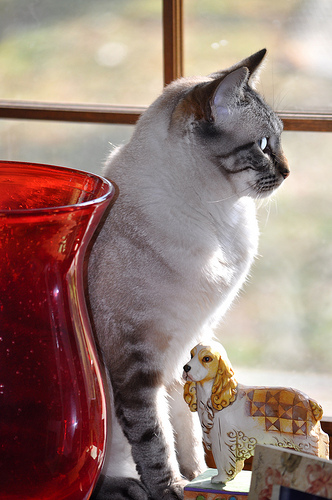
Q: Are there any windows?
A: Yes, there is a window.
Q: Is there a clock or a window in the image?
A: Yes, there is a window.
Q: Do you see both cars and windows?
A: No, there is a window but no cars.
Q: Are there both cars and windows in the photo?
A: No, there is a window but no cars.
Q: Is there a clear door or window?
A: Yes, there is a clear window.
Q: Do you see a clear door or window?
A: Yes, there is a clear window.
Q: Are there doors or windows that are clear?
A: Yes, the window is clear.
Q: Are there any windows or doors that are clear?
A: Yes, the window is clear.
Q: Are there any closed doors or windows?
A: Yes, there is a closed window.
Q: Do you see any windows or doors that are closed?
A: Yes, the window is closed.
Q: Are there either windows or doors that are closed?
A: Yes, the window is closed.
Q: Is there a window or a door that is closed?
A: Yes, the window is closed.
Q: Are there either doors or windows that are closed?
A: Yes, the window is closed.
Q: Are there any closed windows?
A: Yes, there is a closed window.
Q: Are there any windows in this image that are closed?
A: Yes, there is a window that is closed.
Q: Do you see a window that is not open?
A: Yes, there is an closed window.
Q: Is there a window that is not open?
A: Yes, there is an closed window.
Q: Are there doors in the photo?
A: No, there are no doors.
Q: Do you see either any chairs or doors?
A: No, there are no doors or chairs.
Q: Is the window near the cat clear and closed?
A: Yes, the window is clear and closed.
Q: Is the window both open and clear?
A: No, the window is clear but closed.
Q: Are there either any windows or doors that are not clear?
A: No, there is a window but it is clear.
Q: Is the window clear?
A: Yes, the window is clear.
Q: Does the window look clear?
A: Yes, the window is clear.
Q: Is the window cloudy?
A: No, the window is clear.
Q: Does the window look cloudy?
A: No, the window is clear.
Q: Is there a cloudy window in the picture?
A: No, there is a window but it is clear.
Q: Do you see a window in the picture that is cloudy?
A: No, there is a window but it is clear.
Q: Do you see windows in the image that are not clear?
A: No, there is a window but it is clear.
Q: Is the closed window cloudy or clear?
A: The window is clear.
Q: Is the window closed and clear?
A: Yes, the window is closed and clear.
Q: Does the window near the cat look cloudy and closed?
A: No, the window is closed but clear.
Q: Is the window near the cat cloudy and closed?
A: No, the window is closed but clear.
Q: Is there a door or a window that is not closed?
A: No, there is a window but it is closed.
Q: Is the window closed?
A: Yes, the window is closed.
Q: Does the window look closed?
A: Yes, the window is closed.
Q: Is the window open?
A: No, the window is closed.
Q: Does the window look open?
A: No, the window is closed.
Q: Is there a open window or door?
A: No, there is a window but it is closed.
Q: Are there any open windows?
A: No, there is a window but it is closed.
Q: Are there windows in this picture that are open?
A: No, there is a window but it is closed.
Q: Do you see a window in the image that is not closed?
A: No, there is a window but it is closed.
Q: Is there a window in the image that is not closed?
A: No, there is a window but it is closed.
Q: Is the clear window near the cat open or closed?
A: The window is closed.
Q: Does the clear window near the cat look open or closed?
A: The window is closed.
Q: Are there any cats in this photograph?
A: Yes, there is a cat.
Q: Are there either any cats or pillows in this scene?
A: Yes, there is a cat.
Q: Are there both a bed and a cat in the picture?
A: No, there is a cat but no beds.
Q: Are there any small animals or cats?
A: Yes, there is a small cat.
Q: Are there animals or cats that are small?
A: Yes, the cat is small.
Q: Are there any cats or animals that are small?
A: Yes, the cat is small.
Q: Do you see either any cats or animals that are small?
A: Yes, the cat is small.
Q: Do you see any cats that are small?
A: Yes, there is a small cat.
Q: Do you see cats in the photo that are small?
A: Yes, there is a cat that is small.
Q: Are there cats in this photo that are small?
A: Yes, there is a cat that is small.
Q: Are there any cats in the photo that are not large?
A: Yes, there is a small cat.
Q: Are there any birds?
A: No, there are no birds.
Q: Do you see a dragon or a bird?
A: No, there are no birds or dragons.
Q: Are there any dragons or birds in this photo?
A: No, there are no birds or dragons.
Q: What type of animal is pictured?
A: The animal is a cat.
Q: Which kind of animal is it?
A: The animal is a cat.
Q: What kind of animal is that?
A: This is a cat.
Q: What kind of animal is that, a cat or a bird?
A: This is a cat.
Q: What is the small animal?
A: The animal is a cat.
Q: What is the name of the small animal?
A: The animal is a cat.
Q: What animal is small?
A: The animal is a cat.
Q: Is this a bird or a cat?
A: This is a cat.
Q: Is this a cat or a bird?
A: This is a cat.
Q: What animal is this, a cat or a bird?
A: This is a cat.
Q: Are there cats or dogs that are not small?
A: No, there is a cat but it is small.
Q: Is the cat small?
A: Yes, the cat is small.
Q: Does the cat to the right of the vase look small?
A: Yes, the cat is small.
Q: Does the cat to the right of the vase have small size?
A: Yes, the cat is small.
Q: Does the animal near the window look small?
A: Yes, the cat is small.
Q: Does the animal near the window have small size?
A: Yes, the cat is small.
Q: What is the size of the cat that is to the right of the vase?
A: The cat is small.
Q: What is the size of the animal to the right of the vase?
A: The cat is small.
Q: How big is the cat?
A: The cat is small.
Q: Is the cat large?
A: No, the cat is small.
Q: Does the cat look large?
A: No, the cat is small.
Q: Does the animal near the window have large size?
A: No, the cat is small.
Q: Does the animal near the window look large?
A: No, the cat is small.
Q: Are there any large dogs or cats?
A: No, there is a cat but it is small.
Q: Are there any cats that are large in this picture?
A: No, there is a cat but it is small.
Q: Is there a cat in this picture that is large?
A: No, there is a cat but it is small.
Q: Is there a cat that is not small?
A: No, there is a cat but it is small.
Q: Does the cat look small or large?
A: The cat is small.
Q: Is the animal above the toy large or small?
A: The cat is small.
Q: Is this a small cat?
A: Yes, this is a small cat.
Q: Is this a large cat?
A: No, this is a small cat.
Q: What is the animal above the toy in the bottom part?
A: The animal is a cat.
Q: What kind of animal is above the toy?
A: The animal is a cat.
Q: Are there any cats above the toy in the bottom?
A: Yes, there is a cat above the toy.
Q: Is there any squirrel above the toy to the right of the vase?
A: No, there is a cat above the toy.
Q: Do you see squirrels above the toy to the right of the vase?
A: No, there is a cat above the toy.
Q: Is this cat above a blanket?
A: No, the cat is above the toy.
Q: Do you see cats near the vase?
A: Yes, there is a cat near the vase.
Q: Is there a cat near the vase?
A: Yes, there is a cat near the vase.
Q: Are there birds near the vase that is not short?
A: No, there is a cat near the vase.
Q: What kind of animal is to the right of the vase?
A: The animal is a cat.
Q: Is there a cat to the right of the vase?
A: Yes, there is a cat to the right of the vase.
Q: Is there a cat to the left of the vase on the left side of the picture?
A: No, the cat is to the right of the vase.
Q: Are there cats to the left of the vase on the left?
A: No, the cat is to the right of the vase.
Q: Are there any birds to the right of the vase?
A: No, there is a cat to the right of the vase.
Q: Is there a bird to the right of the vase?
A: No, there is a cat to the right of the vase.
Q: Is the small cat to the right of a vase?
A: Yes, the cat is to the right of a vase.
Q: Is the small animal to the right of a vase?
A: Yes, the cat is to the right of a vase.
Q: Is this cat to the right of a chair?
A: No, the cat is to the right of a vase.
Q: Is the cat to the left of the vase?
A: No, the cat is to the right of the vase.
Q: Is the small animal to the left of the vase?
A: No, the cat is to the right of the vase.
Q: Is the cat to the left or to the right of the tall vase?
A: The cat is to the right of the vase.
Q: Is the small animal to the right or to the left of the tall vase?
A: The cat is to the right of the vase.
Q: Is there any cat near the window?
A: Yes, there is a cat near the window.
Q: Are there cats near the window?
A: Yes, there is a cat near the window.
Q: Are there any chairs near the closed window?
A: No, there is a cat near the window.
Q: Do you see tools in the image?
A: No, there are no tools.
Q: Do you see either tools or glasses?
A: No, there are no tools or glasses.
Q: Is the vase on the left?
A: Yes, the vase is on the left of the image.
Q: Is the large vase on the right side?
A: No, the vase is on the left of the image.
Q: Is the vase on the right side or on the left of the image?
A: The vase is on the left of the image.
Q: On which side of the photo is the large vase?
A: The vase is on the left of the image.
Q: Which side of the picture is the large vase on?
A: The vase is on the left of the image.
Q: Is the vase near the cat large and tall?
A: Yes, the vase is large and tall.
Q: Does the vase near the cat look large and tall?
A: Yes, the vase is large and tall.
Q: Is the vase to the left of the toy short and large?
A: No, the vase is large but tall.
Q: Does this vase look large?
A: Yes, the vase is large.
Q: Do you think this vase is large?
A: Yes, the vase is large.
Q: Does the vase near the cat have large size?
A: Yes, the vase is large.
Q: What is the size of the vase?
A: The vase is large.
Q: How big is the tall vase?
A: The vase is large.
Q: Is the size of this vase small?
A: No, the vase is large.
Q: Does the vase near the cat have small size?
A: No, the vase is large.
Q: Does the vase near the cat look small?
A: No, the vase is large.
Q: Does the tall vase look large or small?
A: The vase is large.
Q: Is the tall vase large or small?
A: The vase is large.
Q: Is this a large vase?
A: Yes, this is a large vase.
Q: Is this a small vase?
A: No, this is a large vase.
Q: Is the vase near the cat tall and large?
A: Yes, the vase is tall and large.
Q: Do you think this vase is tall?
A: Yes, the vase is tall.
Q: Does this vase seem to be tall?
A: Yes, the vase is tall.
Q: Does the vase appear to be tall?
A: Yes, the vase is tall.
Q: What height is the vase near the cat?
A: The vase is tall.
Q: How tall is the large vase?
A: The vase is tall.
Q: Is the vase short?
A: No, the vase is tall.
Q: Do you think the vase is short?
A: No, the vase is tall.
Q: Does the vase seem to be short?
A: No, the vase is tall.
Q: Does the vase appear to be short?
A: No, the vase is tall.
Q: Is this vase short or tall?
A: The vase is tall.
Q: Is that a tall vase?
A: Yes, that is a tall vase.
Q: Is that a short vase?
A: No, that is a tall vase.